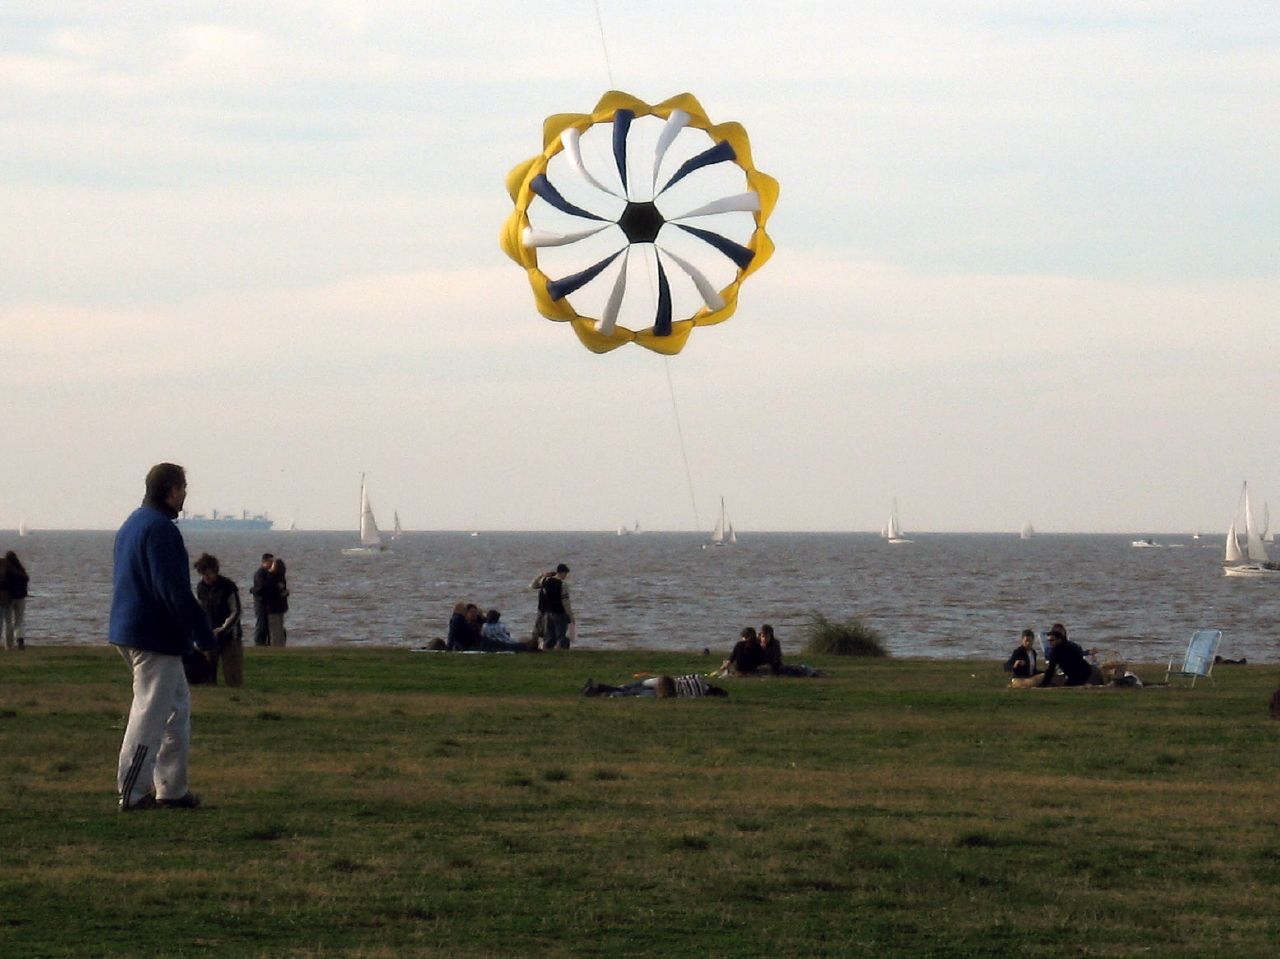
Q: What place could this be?
A: It is a field.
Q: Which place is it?
A: It is a field.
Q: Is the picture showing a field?
A: Yes, it is showing a field.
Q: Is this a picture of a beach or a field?
A: It is showing a field.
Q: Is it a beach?
A: No, it is a field.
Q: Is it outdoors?
A: Yes, it is outdoors.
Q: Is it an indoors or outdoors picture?
A: It is outdoors.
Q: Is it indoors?
A: No, it is outdoors.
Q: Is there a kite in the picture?
A: Yes, there is a kite.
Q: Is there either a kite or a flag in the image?
A: Yes, there is a kite.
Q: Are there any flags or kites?
A: Yes, there is a kite.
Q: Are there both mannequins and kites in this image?
A: No, there is a kite but no mannequins.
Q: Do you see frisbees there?
A: No, there are no frisbees.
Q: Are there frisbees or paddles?
A: No, there are no frisbees or paddles.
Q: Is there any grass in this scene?
A: Yes, there is grass.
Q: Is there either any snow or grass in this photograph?
A: Yes, there is grass.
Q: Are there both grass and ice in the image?
A: No, there is grass but no ice.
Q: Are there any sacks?
A: No, there are no sacks.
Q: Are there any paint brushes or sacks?
A: No, there are no sacks or paint brushes.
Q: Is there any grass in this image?
A: Yes, there is grass.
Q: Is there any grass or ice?
A: Yes, there is grass.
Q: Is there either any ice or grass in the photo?
A: Yes, there is grass.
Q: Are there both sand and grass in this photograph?
A: No, there is grass but no sand.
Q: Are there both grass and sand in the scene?
A: No, there is grass but no sand.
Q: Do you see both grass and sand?
A: No, there is grass but no sand.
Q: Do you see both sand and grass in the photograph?
A: No, there is grass but no sand.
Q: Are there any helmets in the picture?
A: No, there are no helmets.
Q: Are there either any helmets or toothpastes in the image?
A: No, there are no helmets or toothpastes.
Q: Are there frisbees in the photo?
A: No, there are no frisbees.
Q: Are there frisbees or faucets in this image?
A: No, there are no frisbees or faucets.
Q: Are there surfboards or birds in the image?
A: No, there are no surfboards or birds.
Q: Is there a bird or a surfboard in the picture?
A: No, there are no surfboards or birds.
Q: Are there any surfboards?
A: No, there are no surfboards.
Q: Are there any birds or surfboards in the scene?
A: No, there are no surfboards or birds.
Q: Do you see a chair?
A: Yes, there is a chair.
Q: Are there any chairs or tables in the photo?
A: Yes, there is a chair.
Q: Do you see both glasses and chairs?
A: No, there is a chair but no glasses.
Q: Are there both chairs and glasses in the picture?
A: No, there is a chair but no glasses.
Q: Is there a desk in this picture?
A: No, there are no desks.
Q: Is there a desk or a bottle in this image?
A: No, there are no desks or bottles.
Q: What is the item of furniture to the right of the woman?
A: The piece of furniture is a chair.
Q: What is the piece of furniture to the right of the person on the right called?
A: The piece of furniture is a chair.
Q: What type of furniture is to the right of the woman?
A: The piece of furniture is a chair.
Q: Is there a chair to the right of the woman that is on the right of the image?
A: Yes, there is a chair to the right of the woman.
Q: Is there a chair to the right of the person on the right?
A: Yes, there is a chair to the right of the woman.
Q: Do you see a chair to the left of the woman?
A: No, the chair is to the right of the woman.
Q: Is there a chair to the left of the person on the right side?
A: No, the chair is to the right of the woman.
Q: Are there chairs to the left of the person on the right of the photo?
A: No, the chair is to the right of the woman.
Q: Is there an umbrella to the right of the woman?
A: No, there is a chair to the right of the woman.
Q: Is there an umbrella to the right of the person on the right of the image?
A: No, there is a chair to the right of the woman.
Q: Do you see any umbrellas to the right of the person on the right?
A: No, there is a chair to the right of the woman.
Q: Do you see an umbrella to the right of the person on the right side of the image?
A: No, there is a chair to the right of the woman.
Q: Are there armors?
A: No, there are no armors.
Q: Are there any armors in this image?
A: No, there are no armors.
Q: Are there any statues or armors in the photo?
A: No, there are no armors or statues.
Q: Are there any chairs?
A: Yes, there is a chair.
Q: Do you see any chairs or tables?
A: Yes, there is a chair.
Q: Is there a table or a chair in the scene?
A: Yes, there is a chair.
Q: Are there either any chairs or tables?
A: Yes, there is a chair.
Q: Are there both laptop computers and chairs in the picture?
A: No, there is a chair but no laptops.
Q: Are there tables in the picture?
A: No, there are no tables.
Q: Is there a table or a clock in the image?
A: No, there are no tables or clocks.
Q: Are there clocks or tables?
A: No, there are no tables or clocks.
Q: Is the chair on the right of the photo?
A: Yes, the chair is on the right of the image.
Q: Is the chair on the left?
A: No, the chair is on the right of the image.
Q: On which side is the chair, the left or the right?
A: The chair is on the right of the image.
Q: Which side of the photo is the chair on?
A: The chair is on the right of the image.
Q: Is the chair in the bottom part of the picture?
A: Yes, the chair is in the bottom of the image.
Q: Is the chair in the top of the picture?
A: No, the chair is in the bottom of the image.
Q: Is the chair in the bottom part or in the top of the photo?
A: The chair is in the bottom of the image.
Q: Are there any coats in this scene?
A: Yes, there is a coat.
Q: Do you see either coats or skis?
A: Yes, there is a coat.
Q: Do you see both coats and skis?
A: No, there is a coat but no skis.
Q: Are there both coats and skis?
A: No, there is a coat but no skis.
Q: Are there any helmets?
A: No, there are no helmets.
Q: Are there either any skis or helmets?
A: No, there are no helmets or skis.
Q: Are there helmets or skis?
A: No, there are no helmets or skis.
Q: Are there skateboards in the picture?
A: No, there are no skateboards.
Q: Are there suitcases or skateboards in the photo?
A: No, there are no skateboards or suitcases.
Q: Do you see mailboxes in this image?
A: No, there are no mailboxes.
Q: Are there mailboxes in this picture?
A: No, there are no mailboxes.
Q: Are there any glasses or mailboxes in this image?
A: No, there are no mailboxes or glasses.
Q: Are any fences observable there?
A: No, there are no fences.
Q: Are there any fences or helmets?
A: No, there are no fences or helmets.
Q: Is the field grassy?
A: Yes, the field is grassy.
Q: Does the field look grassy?
A: Yes, the field is grassy.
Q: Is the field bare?
A: No, the field is grassy.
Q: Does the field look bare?
A: No, the field is grassy.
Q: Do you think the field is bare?
A: No, the field is grassy.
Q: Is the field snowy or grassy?
A: The field is grassy.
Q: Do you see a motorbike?
A: No, there are no motorcycles.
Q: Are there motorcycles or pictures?
A: No, there are no motorcycles or pictures.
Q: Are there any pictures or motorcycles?
A: No, there are no motorcycles or pictures.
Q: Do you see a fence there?
A: No, there are no fences.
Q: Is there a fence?
A: No, there are no fences.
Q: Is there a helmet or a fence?
A: No, there are no fences or helmets.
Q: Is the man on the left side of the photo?
A: Yes, the man is on the left of the image.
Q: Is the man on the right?
A: No, the man is on the left of the image.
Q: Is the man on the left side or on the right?
A: The man is on the left of the image.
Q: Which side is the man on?
A: The man is on the left of the image.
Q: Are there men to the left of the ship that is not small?
A: Yes, there is a man to the left of the ship.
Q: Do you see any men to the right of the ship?
A: No, the man is to the left of the ship.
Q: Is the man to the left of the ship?
A: Yes, the man is to the left of the ship.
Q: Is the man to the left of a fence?
A: No, the man is to the left of the ship.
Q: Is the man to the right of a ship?
A: No, the man is to the left of a ship.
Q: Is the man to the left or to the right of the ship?
A: The man is to the left of the ship.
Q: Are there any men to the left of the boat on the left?
A: Yes, there is a man to the left of the boat.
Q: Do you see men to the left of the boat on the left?
A: Yes, there is a man to the left of the boat.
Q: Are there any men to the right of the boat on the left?
A: No, the man is to the left of the boat.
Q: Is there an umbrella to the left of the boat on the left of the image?
A: No, there is a man to the left of the boat.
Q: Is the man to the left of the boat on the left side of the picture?
A: Yes, the man is to the left of the boat.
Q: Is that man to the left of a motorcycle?
A: No, the man is to the left of the boat.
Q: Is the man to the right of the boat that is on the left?
A: No, the man is to the left of the boat.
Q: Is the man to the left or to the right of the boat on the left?
A: The man is to the left of the boat.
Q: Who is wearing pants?
A: The man is wearing pants.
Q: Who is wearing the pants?
A: The man is wearing pants.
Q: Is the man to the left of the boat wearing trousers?
A: Yes, the man is wearing trousers.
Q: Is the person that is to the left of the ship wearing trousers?
A: Yes, the man is wearing trousers.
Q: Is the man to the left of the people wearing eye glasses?
A: No, the man is wearing trousers.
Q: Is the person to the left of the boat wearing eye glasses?
A: No, the man is wearing trousers.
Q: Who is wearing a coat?
A: The man is wearing a coat.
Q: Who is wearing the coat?
A: The man is wearing a coat.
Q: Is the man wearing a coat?
A: Yes, the man is wearing a coat.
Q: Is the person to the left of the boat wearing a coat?
A: Yes, the man is wearing a coat.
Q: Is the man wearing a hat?
A: No, the man is wearing a coat.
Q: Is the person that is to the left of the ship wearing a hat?
A: No, the man is wearing a coat.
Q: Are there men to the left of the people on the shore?
A: Yes, there is a man to the left of the people.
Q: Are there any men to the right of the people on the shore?
A: No, the man is to the left of the people.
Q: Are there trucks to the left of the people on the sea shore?
A: No, there is a man to the left of the people.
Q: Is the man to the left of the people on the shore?
A: Yes, the man is to the left of the people.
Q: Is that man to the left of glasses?
A: No, the man is to the left of the people.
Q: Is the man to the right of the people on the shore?
A: No, the man is to the left of the people.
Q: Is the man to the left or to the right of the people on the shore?
A: The man is to the left of the people.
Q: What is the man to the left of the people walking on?
A: The man is walking on the grass.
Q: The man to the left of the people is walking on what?
A: The man is walking on the grass.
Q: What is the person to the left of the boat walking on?
A: The man is walking on the grass.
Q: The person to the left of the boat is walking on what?
A: The man is walking on the grass.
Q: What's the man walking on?
A: The man is walking on the grass.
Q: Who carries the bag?
A: The man carries the bag.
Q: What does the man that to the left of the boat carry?
A: The man carries a bag.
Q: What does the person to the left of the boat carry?
A: The man carries a bag.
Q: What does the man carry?
A: The man carries a bag.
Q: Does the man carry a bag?
A: Yes, the man carries a bag.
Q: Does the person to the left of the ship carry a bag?
A: Yes, the man carries a bag.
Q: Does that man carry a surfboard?
A: No, the man carries a bag.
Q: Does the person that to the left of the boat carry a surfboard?
A: No, the man carries a bag.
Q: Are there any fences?
A: No, there are no fences.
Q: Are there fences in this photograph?
A: No, there are no fences.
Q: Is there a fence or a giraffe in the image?
A: No, there are no fences or giraffes.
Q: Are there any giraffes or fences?
A: No, there are no fences or giraffes.